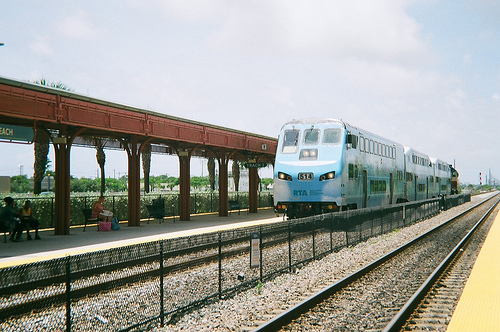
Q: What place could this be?
A: It is a station.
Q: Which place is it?
A: It is a station.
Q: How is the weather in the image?
A: It is clear.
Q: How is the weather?
A: It is clear.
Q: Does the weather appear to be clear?
A: Yes, it is clear.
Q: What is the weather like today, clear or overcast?
A: It is clear.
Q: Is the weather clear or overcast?
A: It is clear.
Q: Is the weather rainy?
A: No, it is clear.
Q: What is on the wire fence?
A: The sign is on the fence.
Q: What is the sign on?
A: The sign is on the fence.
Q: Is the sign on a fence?
A: Yes, the sign is on a fence.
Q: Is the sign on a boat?
A: No, the sign is on a fence.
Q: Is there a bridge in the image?
A: Yes, there is a bridge.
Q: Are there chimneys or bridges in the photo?
A: Yes, there is a bridge.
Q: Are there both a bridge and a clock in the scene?
A: No, there is a bridge but no clocks.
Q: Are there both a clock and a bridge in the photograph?
A: No, there is a bridge but no clocks.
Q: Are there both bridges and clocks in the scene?
A: No, there is a bridge but no clocks.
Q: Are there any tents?
A: No, there are no tents.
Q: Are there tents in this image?
A: No, there are no tents.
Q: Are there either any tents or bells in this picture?
A: No, there are no tents or bells.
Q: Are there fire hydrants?
A: No, there are no fire hydrants.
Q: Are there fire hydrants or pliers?
A: No, there are no fire hydrants or pliers.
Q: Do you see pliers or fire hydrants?
A: No, there are no fire hydrants or pliers.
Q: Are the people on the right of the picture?
A: No, the people are on the left of the image.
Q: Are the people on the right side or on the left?
A: The people are on the left of the image.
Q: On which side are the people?
A: The people are on the left of the image.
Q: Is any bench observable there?
A: Yes, there is a bench.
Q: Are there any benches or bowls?
A: Yes, there is a bench.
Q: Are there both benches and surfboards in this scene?
A: No, there is a bench but no surfboards.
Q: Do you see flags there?
A: No, there are no flags.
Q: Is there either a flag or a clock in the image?
A: No, there are no flags or clocks.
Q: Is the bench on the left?
A: Yes, the bench is on the left of the image.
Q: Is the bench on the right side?
A: No, the bench is on the left of the image.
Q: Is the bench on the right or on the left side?
A: The bench is on the left of the image.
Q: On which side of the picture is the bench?
A: The bench is on the left of the image.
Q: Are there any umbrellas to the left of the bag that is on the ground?
A: No, there is a bench to the left of the bag.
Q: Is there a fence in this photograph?
A: Yes, there is a fence.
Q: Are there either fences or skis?
A: Yes, there is a fence.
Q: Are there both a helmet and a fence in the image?
A: No, there is a fence but no helmets.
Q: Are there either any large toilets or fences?
A: Yes, there is a large fence.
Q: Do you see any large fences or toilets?
A: Yes, there is a large fence.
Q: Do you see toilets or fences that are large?
A: Yes, the fence is large.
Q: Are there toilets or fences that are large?
A: Yes, the fence is large.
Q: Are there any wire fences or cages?
A: Yes, there is a wire fence.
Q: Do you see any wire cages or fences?
A: Yes, there is a wire fence.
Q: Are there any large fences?
A: Yes, there is a large fence.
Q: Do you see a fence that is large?
A: Yes, there is a large fence.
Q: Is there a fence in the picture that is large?
A: Yes, there is a fence that is large.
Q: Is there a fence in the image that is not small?
A: Yes, there is a large fence.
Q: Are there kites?
A: No, there are no kites.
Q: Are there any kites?
A: No, there are no kites.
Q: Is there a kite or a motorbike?
A: No, there are no kites or motorcycles.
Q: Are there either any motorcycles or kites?
A: No, there are no kites or motorcycles.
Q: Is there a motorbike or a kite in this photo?
A: No, there are no kites or motorcycles.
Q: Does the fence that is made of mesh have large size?
A: Yes, the fence is large.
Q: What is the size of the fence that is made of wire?
A: The fence is large.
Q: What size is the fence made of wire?
A: The fence is large.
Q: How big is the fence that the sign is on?
A: The fence is large.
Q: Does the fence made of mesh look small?
A: No, the fence is large.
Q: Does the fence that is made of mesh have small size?
A: No, the fence is large.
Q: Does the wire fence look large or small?
A: The fence is large.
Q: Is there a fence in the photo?
A: Yes, there is a fence.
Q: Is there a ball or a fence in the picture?
A: Yes, there is a fence.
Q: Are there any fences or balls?
A: Yes, there is a fence.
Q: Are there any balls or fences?
A: Yes, there is a fence.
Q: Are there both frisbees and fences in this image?
A: No, there is a fence but no frisbees.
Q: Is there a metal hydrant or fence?
A: Yes, there is a metal fence.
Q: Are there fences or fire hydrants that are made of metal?
A: Yes, the fence is made of metal.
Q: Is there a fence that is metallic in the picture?
A: Yes, there is a metal fence.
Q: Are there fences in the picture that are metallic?
A: Yes, there is a fence that is metallic.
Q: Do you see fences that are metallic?
A: Yes, there is a fence that is metallic.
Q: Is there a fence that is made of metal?
A: Yes, there is a fence that is made of metal.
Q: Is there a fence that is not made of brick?
A: Yes, there is a fence that is made of metal.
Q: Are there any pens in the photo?
A: No, there are no pens.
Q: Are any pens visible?
A: No, there are no pens.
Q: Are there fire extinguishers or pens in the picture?
A: No, there are no pens or fire extinguishers.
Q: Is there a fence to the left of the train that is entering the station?
A: Yes, there is a fence to the left of the train.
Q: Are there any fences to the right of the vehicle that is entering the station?
A: No, the fence is to the left of the train.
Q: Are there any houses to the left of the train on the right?
A: No, there is a fence to the left of the train.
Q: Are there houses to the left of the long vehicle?
A: No, there is a fence to the left of the train.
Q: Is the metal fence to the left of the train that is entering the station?
A: Yes, the fence is to the left of the train.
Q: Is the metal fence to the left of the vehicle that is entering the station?
A: Yes, the fence is to the left of the train.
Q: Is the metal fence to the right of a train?
A: No, the fence is to the left of a train.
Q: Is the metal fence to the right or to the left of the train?
A: The fence is to the left of the train.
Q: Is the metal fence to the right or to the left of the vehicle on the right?
A: The fence is to the left of the train.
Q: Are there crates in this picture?
A: No, there are no crates.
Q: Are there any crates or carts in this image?
A: No, there are no crates or carts.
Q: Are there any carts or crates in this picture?
A: No, there are no crates or carts.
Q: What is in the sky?
A: The clouds are in the sky.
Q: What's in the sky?
A: The clouds are in the sky.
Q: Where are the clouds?
A: The clouds are in the sky.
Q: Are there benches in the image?
A: Yes, there is a bench.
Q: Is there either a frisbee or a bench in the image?
A: Yes, there is a bench.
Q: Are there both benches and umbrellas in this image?
A: No, there is a bench but no umbrellas.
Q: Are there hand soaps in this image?
A: No, there are no hand soaps.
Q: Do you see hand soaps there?
A: No, there are no hand soaps.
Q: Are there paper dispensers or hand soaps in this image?
A: No, there are no hand soaps or paper dispensers.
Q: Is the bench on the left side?
A: Yes, the bench is on the left of the image.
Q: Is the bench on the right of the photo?
A: No, the bench is on the left of the image.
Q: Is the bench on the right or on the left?
A: The bench is on the left of the image.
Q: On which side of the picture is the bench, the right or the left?
A: The bench is on the left of the image.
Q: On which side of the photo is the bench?
A: The bench is on the left of the image.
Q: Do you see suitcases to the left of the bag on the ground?
A: No, there is a bench to the left of the bag.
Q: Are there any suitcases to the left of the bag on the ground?
A: No, there is a bench to the left of the bag.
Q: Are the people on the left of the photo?
A: Yes, the people are on the left of the image.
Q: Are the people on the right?
A: No, the people are on the left of the image.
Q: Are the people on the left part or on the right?
A: The people are on the left of the image.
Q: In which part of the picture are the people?
A: The people are on the left of the image.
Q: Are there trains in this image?
A: Yes, there is a train.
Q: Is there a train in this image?
A: Yes, there is a train.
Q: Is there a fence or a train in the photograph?
A: Yes, there is a train.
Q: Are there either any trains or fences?
A: Yes, there is a train.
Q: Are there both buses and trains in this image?
A: No, there is a train but no buses.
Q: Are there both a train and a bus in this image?
A: No, there is a train but no buses.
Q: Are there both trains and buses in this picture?
A: No, there is a train but no buses.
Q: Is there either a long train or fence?
A: Yes, there is a long train.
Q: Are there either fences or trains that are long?
A: Yes, the train is long.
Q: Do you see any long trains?
A: Yes, there is a long train.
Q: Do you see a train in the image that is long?
A: Yes, there is a train that is long.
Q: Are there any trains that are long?
A: Yes, there is a train that is long.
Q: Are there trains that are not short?
A: Yes, there is a long train.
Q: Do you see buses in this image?
A: No, there are no buses.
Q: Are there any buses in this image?
A: No, there are no buses.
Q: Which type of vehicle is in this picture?
A: The vehicle is a train.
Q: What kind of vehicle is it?
A: The vehicle is a train.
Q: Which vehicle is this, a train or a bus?
A: That is a train.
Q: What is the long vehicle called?
A: The vehicle is a train.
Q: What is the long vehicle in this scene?
A: The vehicle is a train.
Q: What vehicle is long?
A: The vehicle is a train.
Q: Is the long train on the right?
A: Yes, the train is on the right of the image.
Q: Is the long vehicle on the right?
A: Yes, the train is on the right of the image.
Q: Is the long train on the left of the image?
A: No, the train is on the right of the image.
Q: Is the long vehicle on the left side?
A: No, the train is on the right of the image.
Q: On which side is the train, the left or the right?
A: The train is on the right of the image.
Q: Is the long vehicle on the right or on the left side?
A: The train is on the right of the image.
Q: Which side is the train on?
A: The train is on the right of the image.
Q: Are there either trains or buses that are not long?
A: No, there is a train but it is long.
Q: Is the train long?
A: Yes, the train is long.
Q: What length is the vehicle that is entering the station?
A: The train is long.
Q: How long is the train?
A: The train is long.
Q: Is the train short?
A: No, the train is long.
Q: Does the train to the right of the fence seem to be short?
A: No, the train is long.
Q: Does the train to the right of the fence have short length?
A: No, the train is long.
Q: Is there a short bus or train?
A: No, there is a train but it is long.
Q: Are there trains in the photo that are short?
A: No, there is a train but it is long.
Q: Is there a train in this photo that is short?
A: No, there is a train but it is long.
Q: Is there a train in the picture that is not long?
A: No, there is a train but it is long.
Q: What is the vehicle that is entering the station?
A: The vehicle is a train.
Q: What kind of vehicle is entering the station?
A: The vehicle is a train.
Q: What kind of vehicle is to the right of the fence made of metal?
A: The vehicle is a train.